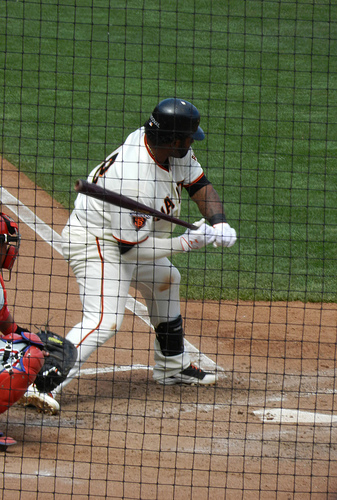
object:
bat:
[78, 180, 201, 230]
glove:
[32, 333, 76, 387]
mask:
[0, 213, 19, 272]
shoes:
[26, 364, 61, 413]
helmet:
[148, 97, 204, 143]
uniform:
[61, 129, 204, 394]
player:
[23, 98, 237, 416]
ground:
[0, 0, 336, 499]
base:
[256, 404, 334, 440]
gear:
[153, 315, 184, 353]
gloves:
[210, 221, 236, 249]